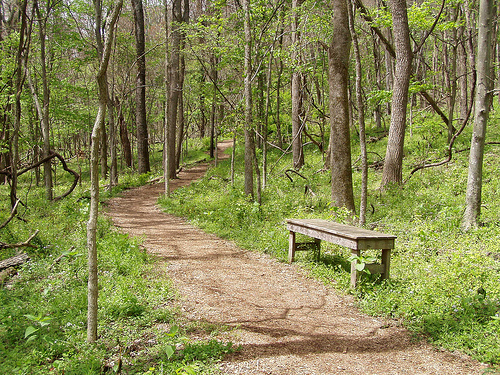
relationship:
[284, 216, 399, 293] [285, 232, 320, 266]
legs of bench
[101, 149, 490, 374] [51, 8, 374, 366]
dirt path in forest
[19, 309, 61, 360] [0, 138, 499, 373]
plant on ground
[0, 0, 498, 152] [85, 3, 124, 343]
leaves of a tree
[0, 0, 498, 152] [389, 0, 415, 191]
leaves of a tree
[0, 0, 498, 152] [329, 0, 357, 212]
leaves of a tree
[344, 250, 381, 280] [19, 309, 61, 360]
weeds in plant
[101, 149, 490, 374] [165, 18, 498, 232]
dirt path winds through trees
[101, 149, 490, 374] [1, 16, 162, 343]
dirt path winds through trees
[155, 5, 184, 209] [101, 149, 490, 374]
tree growing in dirt path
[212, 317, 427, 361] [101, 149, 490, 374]
shadow on dirt path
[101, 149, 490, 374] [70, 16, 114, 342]
dirt path between trees